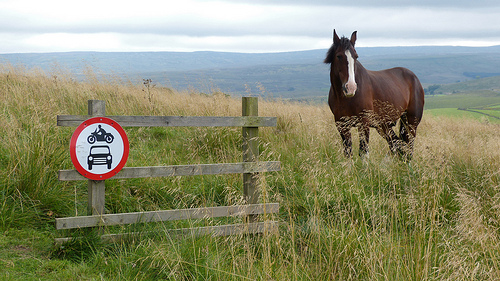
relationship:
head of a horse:
[324, 20, 371, 99] [322, 27, 427, 169]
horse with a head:
[322, 27, 427, 169] [324, 20, 371, 99]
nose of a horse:
[340, 79, 360, 102] [322, 27, 427, 169]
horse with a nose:
[322, 27, 427, 169] [340, 79, 360, 102]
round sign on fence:
[68, 114, 127, 178] [46, 86, 287, 253]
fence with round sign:
[46, 86, 287, 253] [68, 114, 127, 178]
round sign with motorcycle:
[68, 114, 127, 178] [86, 123, 115, 145]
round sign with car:
[68, 114, 127, 178] [87, 145, 113, 171]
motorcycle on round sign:
[86, 123, 115, 145] [68, 114, 127, 178]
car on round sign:
[87, 145, 113, 171] [68, 114, 127, 178]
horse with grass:
[321, 33, 425, 169] [9, 97, 486, 279]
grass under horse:
[9, 97, 486, 279] [321, 33, 425, 169]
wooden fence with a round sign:
[55, 93, 280, 238] [68, 114, 127, 178]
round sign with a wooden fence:
[68, 114, 127, 178] [55, 93, 280, 238]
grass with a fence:
[0, 96, 499, 281] [46, 86, 287, 253]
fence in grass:
[46, 86, 287, 253] [0, 96, 499, 281]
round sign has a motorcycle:
[68, 114, 127, 178] [84, 117, 115, 146]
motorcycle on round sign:
[84, 117, 115, 146] [68, 114, 127, 178]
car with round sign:
[87, 145, 111, 170] [68, 114, 127, 178]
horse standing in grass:
[322, 27, 427, 169] [41, 63, 496, 274]